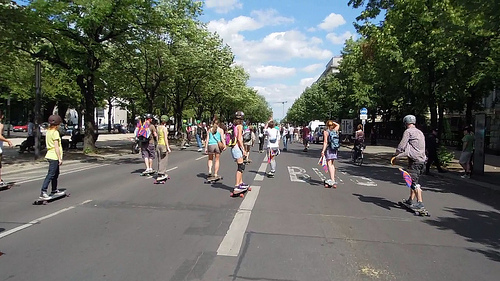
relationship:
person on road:
[231, 113, 253, 202] [103, 99, 437, 228]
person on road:
[210, 111, 225, 182] [103, 99, 437, 228]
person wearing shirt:
[51, 118, 65, 200] [46, 132, 67, 161]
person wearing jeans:
[51, 118, 65, 200] [40, 158, 63, 195]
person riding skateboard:
[389, 115, 435, 220] [397, 198, 425, 217]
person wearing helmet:
[231, 113, 253, 202] [235, 108, 244, 118]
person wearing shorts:
[231, 113, 253, 202] [230, 146, 244, 157]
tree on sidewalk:
[367, 8, 467, 184] [365, 126, 499, 186]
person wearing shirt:
[210, 111, 225, 182] [206, 130, 220, 142]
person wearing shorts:
[210, 111, 225, 182] [205, 147, 220, 152]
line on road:
[225, 119, 273, 227] [103, 99, 437, 228]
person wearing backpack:
[320, 123, 348, 186] [327, 126, 341, 148]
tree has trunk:
[367, 8, 467, 184] [424, 96, 442, 139]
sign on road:
[336, 120, 356, 148] [103, 99, 437, 228]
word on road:
[289, 161, 379, 194] [103, 99, 437, 228]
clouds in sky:
[213, 18, 296, 71] [162, 3, 360, 127]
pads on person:
[241, 163, 246, 170] [231, 113, 253, 202]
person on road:
[51, 118, 65, 200] [103, 99, 437, 228]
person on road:
[320, 123, 348, 186] [103, 99, 437, 228]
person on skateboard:
[320, 123, 348, 186] [325, 177, 334, 191]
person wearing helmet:
[389, 115, 435, 220] [400, 111, 417, 123]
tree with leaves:
[367, 8, 467, 184] [426, 22, 474, 59]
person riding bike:
[350, 128, 367, 168] [348, 145, 365, 165]